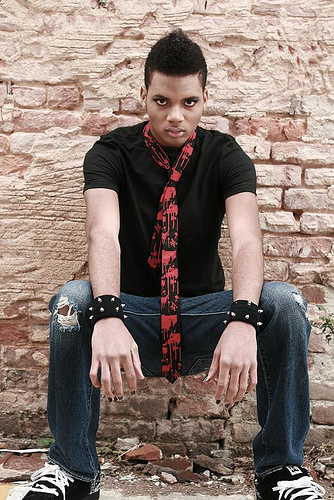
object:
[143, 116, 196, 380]
tie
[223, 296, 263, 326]
cuffs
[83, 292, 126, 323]
cuffs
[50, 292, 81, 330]
hole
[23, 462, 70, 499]
shoe laces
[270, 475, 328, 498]
shoe laces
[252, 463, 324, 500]
shoe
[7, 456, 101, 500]
shoe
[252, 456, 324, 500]
feet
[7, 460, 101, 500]
feet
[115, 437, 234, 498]
bricks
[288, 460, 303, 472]
logo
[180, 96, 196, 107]
liner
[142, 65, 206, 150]
face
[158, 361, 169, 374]
spot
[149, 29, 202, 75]
cut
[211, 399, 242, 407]
polish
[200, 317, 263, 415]
hand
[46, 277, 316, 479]
jeans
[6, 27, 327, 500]
man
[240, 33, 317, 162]
wall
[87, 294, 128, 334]
bands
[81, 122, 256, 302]
shirt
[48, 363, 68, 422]
material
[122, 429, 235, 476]
broken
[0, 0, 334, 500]
ground